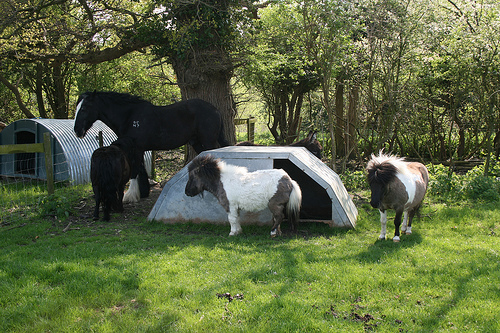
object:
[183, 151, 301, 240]
horse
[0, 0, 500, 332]
field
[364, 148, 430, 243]
horse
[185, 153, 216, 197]
head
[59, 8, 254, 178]
tree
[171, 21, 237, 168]
trunk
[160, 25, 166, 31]
leaves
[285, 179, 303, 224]
tail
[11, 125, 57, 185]
front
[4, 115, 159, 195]
shed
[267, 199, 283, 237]
leg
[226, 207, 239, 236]
leg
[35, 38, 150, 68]
limb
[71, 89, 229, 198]
horse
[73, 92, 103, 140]
face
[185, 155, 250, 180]
mane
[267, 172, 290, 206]
back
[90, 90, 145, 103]
mane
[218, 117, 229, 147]
tail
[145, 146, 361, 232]
building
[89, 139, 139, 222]
animal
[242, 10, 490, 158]
trees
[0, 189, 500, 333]
grass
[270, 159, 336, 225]
door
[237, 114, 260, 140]
fence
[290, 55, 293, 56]
leaves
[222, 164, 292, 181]
backside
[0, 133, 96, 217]
fence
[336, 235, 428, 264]
shadow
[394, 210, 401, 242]
legs